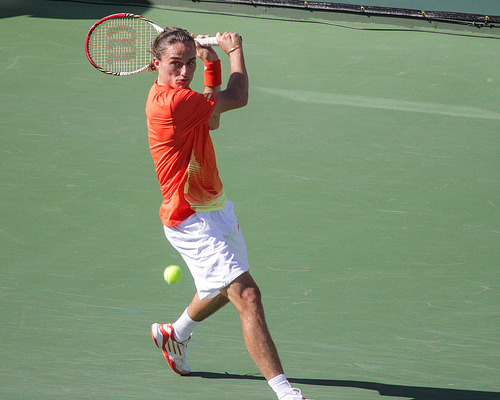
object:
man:
[144, 25, 315, 400]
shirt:
[143, 77, 225, 228]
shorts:
[161, 195, 250, 301]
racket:
[83, 10, 222, 77]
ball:
[159, 263, 184, 286]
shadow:
[178, 369, 500, 399]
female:
[145, 25, 311, 399]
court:
[0, 5, 499, 399]